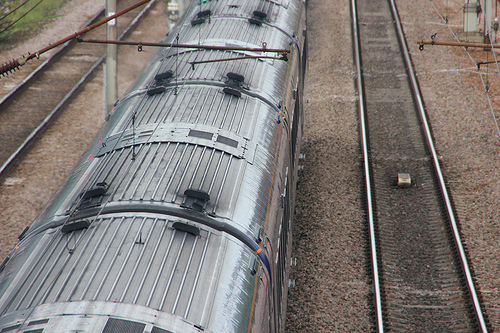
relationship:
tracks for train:
[358, 61, 428, 159] [45, 21, 260, 322]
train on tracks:
[45, 21, 260, 322] [358, 61, 428, 159]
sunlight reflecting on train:
[233, 194, 258, 223] [45, 21, 260, 322]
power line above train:
[35, 43, 69, 56] [45, 21, 260, 322]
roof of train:
[85, 236, 189, 295] [45, 21, 260, 322]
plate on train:
[112, 128, 252, 154] [45, 21, 260, 322]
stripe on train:
[276, 128, 282, 171] [45, 21, 260, 322]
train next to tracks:
[45, 21, 260, 322] [358, 61, 428, 159]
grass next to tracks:
[14, 10, 39, 26] [21, 68, 73, 111]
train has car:
[45, 21, 260, 322] [209, 4, 288, 24]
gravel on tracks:
[305, 11, 361, 331] [358, 61, 428, 159]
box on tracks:
[395, 169, 415, 186] [358, 61, 428, 159]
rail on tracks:
[394, 3, 411, 43] [358, 61, 428, 159]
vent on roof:
[188, 126, 214, 141] [85, 236, 189, 295]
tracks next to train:
[358, 61, 428, 159] [45, 21, 260, 322]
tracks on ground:
[358, 61, 428, 159] [445, 77, 483, 152]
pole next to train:
[420, 35, 497, 51] [45, 21, 260, 322]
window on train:
[274, 253, 287, 279] [45, 21, 260, 322]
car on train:
[209, 4, 288, 24] [45, 21, 260, 322]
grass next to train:
[14, 10, 39, 26] [45, 21, 260, 322]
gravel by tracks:
[305, 11, 361, 331] [358, 61, 428, 159]